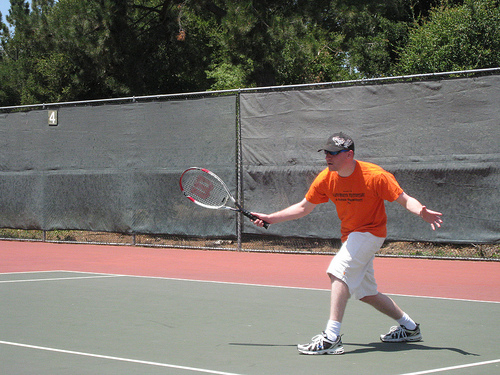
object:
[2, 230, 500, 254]
dirt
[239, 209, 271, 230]
handle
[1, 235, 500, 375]
court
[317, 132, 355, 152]
cap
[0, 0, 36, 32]
skies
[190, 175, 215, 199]
logo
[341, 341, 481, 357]
shadow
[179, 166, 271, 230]
racket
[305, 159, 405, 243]
shirt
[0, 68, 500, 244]
fence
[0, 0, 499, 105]
trees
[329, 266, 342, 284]
knee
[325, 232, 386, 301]
shorts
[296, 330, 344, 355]
shoe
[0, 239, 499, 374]
tennis court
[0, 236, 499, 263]
border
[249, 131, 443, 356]
man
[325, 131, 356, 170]
man's head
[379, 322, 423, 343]
sneaker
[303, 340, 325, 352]
stripes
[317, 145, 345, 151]
sun visor